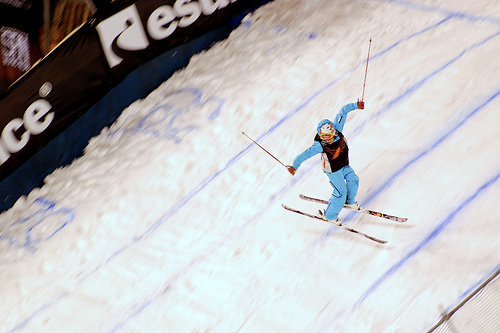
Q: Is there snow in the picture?
A: Yes, there is snow.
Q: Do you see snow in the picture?
A: Yes, there is snow.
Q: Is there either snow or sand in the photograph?
A: Yes, there is snow.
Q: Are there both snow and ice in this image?
A: No, there is snow but no ice.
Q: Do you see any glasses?
A: No, there are no glasses.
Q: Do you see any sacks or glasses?
A: No, there are no glasses or sacks.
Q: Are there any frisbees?
A: No, there are no frisbees.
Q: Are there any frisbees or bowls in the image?
A: No, there are no frisbees or bowls.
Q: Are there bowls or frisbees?
A: No, there are no frisbees or bowls.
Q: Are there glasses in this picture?
A: No, there are no glasses.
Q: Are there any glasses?
A: No, there are no glasses.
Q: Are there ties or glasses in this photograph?
A: No, there are no glasses or ties.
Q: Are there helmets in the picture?
A: Yes, there is a helmet.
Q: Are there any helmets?
A: Yes, there is a helmet.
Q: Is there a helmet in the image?
A: Yes, there is a helmet.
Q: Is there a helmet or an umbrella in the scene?
A: Yes, there is a helmet.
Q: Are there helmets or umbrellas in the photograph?
A: Yes, there is a helmet.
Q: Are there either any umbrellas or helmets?
A: Yes, there is a helmet.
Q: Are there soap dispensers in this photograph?
A: No, there are no soap dispensers.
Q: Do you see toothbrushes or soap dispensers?
A: No, there are no soap dispensers or toothbrushes.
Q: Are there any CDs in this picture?
A: No, there are no cds.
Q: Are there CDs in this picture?
A: No, there are no cds.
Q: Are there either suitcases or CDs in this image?
A: No, there are no CDs or suitcases.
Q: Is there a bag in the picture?
A: No, there are no bags.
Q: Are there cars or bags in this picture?
A: No, there are no bags or cars.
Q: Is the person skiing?
A: Yes, the person is skiing.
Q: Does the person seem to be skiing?
A: Yes, the person is skiing.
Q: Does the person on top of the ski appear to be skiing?
A: Yes, the person is skiing.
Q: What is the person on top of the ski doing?
A: The person is skiing.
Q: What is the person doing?
A: The person is skiing.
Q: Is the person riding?
A: No, the person is skiing.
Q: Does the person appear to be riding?
A: No, the person is skiing.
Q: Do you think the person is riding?
A: No, the person is skiing.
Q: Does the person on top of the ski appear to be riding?
A: No, the person is skiing.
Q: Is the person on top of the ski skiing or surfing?
A: The person is skiing.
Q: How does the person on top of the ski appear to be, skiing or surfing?
A: The person is skiing.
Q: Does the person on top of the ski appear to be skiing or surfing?
A: The person is skiing.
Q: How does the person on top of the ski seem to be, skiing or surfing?
A: The person is skiing.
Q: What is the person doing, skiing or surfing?
A: The person is skiing.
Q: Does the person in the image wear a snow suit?
A: Yes, the person wears a snow suit.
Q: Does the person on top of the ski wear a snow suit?
A: Yes, the person wears a snow suit.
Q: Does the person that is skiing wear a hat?
A: No, the person wears a snow suit.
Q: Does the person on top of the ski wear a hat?
A: No, the person wears a snow suit.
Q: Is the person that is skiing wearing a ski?
A: Yes, the person is wearing a ski.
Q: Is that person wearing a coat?
A: No, the person is wearing a ski.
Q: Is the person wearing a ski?
A: Yes, the person is wearing a ski.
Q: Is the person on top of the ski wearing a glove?
A: Yes, the person is wearing a glove.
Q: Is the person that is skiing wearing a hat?
A: No, the person is wearing a glove.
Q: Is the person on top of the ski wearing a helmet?
A: Yes, the person is wearing a helmet.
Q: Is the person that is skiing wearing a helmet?
A: Yes, the person is wearing a helmet.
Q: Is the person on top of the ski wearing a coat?
A: No, the person is wearing a helmet.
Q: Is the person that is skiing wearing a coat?
A: No, the person is wearing a helmet.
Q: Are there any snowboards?
A: No, there are no snowboards.